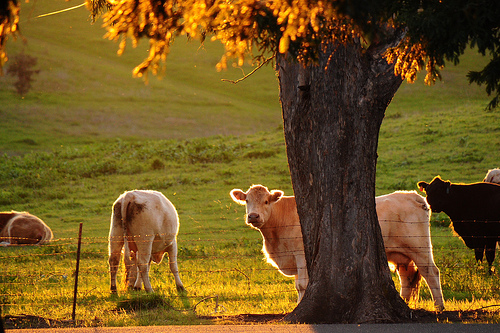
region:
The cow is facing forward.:
[227, 183, 287, 226]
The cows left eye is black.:
[244, 197, 251, 205]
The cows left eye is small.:
[243, 196, 253, 205]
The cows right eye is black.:
[262, 198, 271, 208]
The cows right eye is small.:
[263, 196, 271, 207]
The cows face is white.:
[228, 180, 285, 229]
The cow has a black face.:
[416, 178, 459, 211]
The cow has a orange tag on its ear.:
[415, 170, 450, 214]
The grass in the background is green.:
[56, 156, 108, 198]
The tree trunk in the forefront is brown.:
[276, 66, 409, 317]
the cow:
[101, 178, 173, 241]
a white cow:
[222, 181, 294, 229]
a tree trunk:
[276, 73, 383, 318]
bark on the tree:
[304, 115, 377, 259]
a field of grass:
[43, 43, 117, 130]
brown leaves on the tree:
[178, 13, 285, 53]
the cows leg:
[415, 255, 458, 308]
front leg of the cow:
[170, 260, 189, 290]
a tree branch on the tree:
[217, 74, 267, 84]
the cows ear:
[267, 186, 287, 203]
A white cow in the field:
[79, 179, 204, 296]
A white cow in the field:
[244, 162, 445, 294]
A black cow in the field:
[418, 171, 498, 226]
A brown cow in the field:
[5, 200, 54, 246]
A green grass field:
[172, 245, 259, 305]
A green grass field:
[20, 245, 103, 301]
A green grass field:
[158, 150, 239, 217]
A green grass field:
[7, 139, 99, 184]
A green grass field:
[413, 109, 497, 144]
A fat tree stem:
[256, 43, 428, 313]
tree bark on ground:
[281, 63, 396, 324]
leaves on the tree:
[186, 0, 254, 56]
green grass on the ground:
[86, 147, 177, 178]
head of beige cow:
[229, 181, 281, 228]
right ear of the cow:
[223, 184, 247, 202]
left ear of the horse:
[268, 188, 283, 203]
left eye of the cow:
[260, 195, 267, 211]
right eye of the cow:
[244, 197, 251, 207]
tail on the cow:
[123, 190, 131, 232]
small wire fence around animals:
[0, 226, 83, 331]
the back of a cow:
[93, 110, 198, 295]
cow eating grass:
[103, 156, 203, 312]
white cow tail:
[110, 195, 135, 285]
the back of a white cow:
[104, 175, 194, 301]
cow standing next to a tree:
[210, 156, 445, 321]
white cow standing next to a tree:
[220, 156, 438, 326]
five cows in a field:
[5, 160, 497, 326]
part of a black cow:
[420, 160, 499, 275]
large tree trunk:
[287, 35, 388, 321]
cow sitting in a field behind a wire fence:
[2, 171, 64, 328]